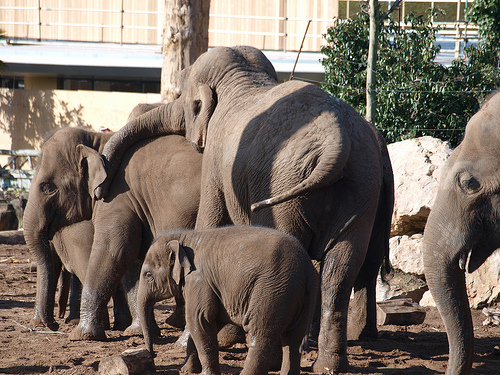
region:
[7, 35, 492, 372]
a herd of elephants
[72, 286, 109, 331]
white powder on the leg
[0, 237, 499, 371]
dirt on the ground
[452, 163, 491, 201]
eye on the side of the face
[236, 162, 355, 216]
tail is swinging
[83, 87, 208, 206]
trunk laying on another elephant's back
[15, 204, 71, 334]
trunk hanging down to the ground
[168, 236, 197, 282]
large ear on the side of the head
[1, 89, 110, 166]
shadows on the wall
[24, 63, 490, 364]
a small herd of elephants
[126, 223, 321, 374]
a baby elephant outside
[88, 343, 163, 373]
a piece of wood on the ground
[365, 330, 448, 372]
shadows on the dirt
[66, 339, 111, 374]
some prints in the dirt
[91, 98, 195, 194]
an elephant trunk on another elephant's back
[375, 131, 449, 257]
a large boulder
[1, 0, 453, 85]
a balcony with a fence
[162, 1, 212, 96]
a bare tree trunk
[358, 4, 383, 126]
a crooked fence post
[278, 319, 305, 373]
grey colored elephant leg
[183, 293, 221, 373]
grey colored elephant leg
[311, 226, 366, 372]
grey colored elephant leg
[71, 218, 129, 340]
grey colored elephant leg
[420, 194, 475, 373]
grey colored elephant trunk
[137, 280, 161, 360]
grey colored elephant trunk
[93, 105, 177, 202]
grey colored elephant trunk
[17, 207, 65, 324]
grey colored elephant trunk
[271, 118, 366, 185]
light on back of elephant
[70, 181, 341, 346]
baby elephant in photo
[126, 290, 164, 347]
trunk of the elephant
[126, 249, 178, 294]
eye of the elephant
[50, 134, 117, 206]
ear of the elephant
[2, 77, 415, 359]
many elephants in the photo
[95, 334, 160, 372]
rock on the ground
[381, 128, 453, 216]
rocks next to animals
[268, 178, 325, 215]
Bunch of elephants by a pole.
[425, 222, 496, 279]
Bunch of elephants by a pole.